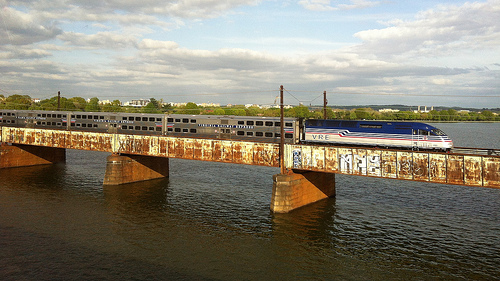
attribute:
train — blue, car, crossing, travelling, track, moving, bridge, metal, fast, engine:
[224, 103, 464, 177]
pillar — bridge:
[242, 154, 355, 231]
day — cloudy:
[128, 7, 264, 104]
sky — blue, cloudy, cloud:
[258, 14, 372, 49]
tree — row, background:
[364, 101, 463, 124]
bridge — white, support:
[305, 148, 417, 186]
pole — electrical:
[266, 73, 294, 168]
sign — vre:
[312, 125, 334, 145]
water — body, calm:
[329, 175, 432, 242]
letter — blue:
[305, 126, 341, 147]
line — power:
[227, 76, 301, 136]